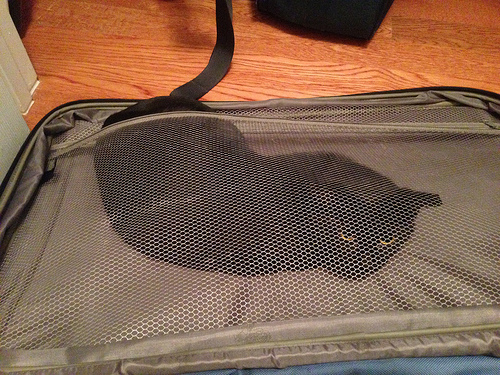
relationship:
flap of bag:
[90, 256, 137, 312] [3, 294, 205, 358]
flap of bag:
[0, 103, 499, 363] [1, 83, 499, 373]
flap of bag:
[53, 102, 489, 322] [1, 83, 499, 373]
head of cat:
[305, 182, 435, 272] [150, 92, 462, 297]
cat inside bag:
[99, 104, 467, 298] [1, 83, 499, 373]